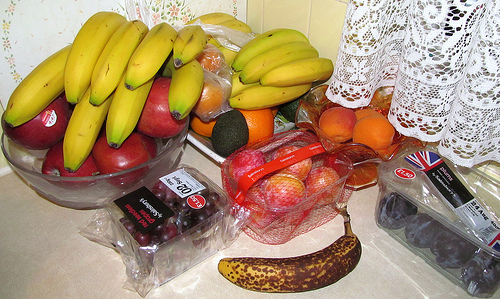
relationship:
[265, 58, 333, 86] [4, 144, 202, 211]
banana in bowl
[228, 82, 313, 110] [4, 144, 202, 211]
banana in bowl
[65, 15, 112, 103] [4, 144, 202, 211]
banana in bowl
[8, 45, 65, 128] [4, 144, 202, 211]
banana in bowl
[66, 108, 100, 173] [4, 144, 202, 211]
banana in bowl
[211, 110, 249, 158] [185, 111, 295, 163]
avocado in dish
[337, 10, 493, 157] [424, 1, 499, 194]
curatin on window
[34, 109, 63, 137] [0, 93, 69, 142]
sticker on apple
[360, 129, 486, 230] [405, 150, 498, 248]
union jack on sticker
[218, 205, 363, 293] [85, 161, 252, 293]
banana next to grapes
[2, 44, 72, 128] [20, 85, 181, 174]
banana on apples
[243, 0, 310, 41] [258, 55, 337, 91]
tile behind banana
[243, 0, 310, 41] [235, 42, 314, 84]
tile behind banana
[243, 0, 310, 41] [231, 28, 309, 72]
tile behind banana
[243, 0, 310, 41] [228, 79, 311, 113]
tile behind banana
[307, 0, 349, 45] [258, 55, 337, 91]
tile behind banana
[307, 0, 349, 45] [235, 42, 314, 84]
tile behind banana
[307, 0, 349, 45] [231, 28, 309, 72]
tile behind banana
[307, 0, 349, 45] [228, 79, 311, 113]
tile behind banana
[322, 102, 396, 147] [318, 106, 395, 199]
apricots in orange bowl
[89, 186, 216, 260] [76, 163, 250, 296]
grapes in package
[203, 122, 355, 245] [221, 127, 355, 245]
nectarines in package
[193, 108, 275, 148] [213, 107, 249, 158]
orange behind avocado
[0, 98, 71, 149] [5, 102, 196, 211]
apple in bowl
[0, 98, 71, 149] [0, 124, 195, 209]
apple in a bowl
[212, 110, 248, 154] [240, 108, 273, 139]
avocado front oranges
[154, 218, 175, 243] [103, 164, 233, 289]
grape inside box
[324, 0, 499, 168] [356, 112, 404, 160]
curatin above peach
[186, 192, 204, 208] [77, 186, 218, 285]
sticker on plastic box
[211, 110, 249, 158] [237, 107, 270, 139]
avocado next to orange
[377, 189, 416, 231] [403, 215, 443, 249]
plum next to plum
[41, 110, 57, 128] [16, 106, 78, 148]
sticker on apple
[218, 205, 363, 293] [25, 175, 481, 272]
banana on counter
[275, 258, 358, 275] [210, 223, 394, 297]
brown parts of banana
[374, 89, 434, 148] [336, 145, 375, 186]
peaches in bowl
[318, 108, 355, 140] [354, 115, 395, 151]
peach next to peach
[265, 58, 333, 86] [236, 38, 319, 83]
banana next to banana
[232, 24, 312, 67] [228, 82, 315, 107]
banana next to banana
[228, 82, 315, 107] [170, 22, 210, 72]
banana next to banana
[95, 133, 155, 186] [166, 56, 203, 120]
apple below banana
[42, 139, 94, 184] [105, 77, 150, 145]
apple below banana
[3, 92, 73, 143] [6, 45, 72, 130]
apple below banana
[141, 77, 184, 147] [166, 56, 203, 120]
apple below banana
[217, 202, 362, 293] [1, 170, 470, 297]
banana on a counter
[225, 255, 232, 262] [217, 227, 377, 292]
brown spots on a banana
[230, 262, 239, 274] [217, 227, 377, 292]
brown spots on a banana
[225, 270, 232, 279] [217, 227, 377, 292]
brown spots on a banana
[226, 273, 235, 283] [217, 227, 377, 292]
brown spots on a banana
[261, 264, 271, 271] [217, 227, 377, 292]
brown spots on a banana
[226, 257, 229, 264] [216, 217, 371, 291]
brown spots on a banana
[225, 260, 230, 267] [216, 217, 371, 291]
brown spots on a banana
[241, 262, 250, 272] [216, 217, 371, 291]
brown spots on a banana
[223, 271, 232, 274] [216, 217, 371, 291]
brown spots on a banana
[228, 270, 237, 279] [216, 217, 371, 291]
brown spots on a banana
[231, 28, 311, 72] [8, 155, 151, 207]
banana in a bowl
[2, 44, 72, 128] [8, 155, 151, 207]
banana in a bowl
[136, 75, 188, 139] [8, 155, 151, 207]
apple in a bowl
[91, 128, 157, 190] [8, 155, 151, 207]
apple in a bowl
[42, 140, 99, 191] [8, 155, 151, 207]
apple in a bowl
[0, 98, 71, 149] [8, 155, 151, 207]
apple in a bowl